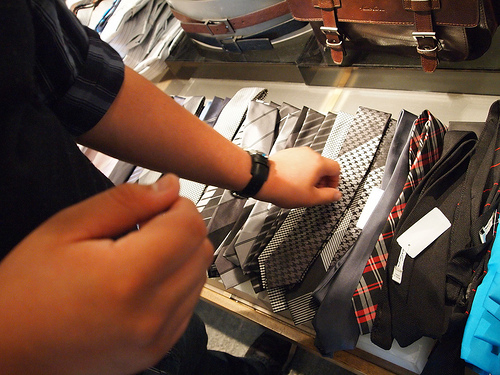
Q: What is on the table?
A: Ties.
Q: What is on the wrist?
A: Watch.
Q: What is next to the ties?
A: The man.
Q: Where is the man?
A: Next to ties.